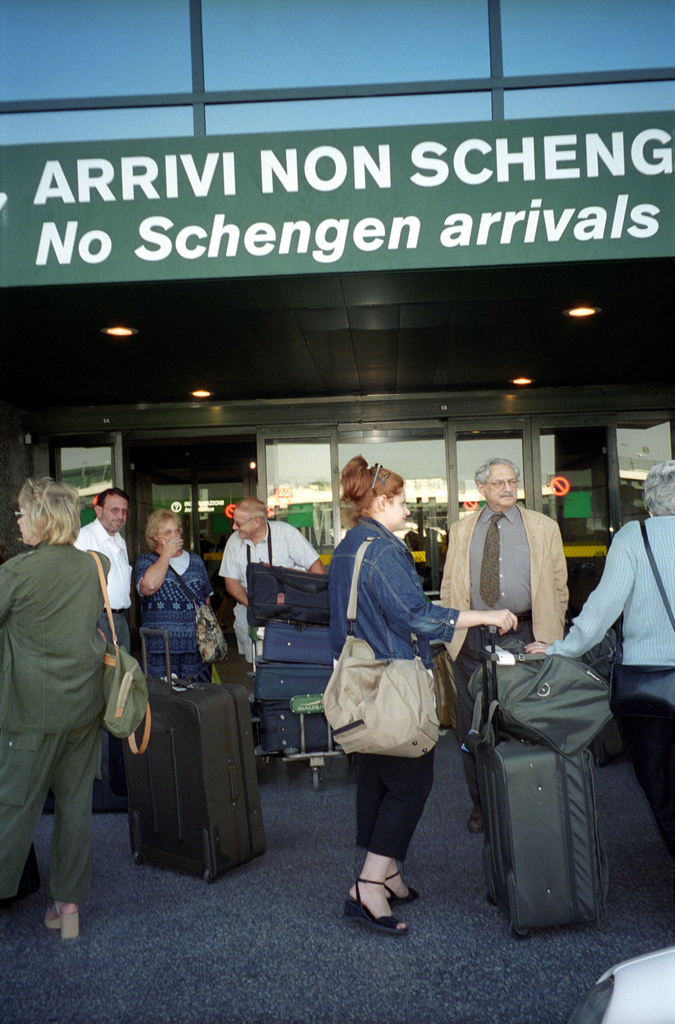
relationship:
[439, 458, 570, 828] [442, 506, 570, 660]
man in jacket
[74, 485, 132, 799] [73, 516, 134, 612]
man wearing shirt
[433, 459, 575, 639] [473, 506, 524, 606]
man wearing tie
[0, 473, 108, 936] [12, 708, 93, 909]
woman wearing pants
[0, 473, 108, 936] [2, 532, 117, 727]
woman wearing top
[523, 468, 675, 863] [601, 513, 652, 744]
woman with purse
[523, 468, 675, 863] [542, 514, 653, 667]
woman with sweater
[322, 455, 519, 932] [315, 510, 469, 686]
woman wearing jacket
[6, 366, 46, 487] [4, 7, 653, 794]
wall on building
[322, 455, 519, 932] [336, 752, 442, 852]
woman wearing pants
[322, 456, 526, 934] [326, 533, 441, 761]
woman holding bag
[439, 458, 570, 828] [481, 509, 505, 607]
man wearing tie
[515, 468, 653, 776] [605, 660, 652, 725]
woman holding purse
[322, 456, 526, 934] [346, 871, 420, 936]
woman wearing sandals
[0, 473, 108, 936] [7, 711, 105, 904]
woman wearing pants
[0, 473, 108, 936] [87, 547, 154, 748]
woman holding bag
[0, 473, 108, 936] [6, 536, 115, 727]
woman wearing jacket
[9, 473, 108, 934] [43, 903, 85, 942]
woman wearing shoes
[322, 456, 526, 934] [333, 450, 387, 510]
woman with hair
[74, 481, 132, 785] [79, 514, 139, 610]
man in shirt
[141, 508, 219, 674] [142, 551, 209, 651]
woman in shirt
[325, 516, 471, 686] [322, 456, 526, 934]
jacket on woman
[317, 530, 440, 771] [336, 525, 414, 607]
bag on shoulder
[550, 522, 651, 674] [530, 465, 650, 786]
jacket on woman